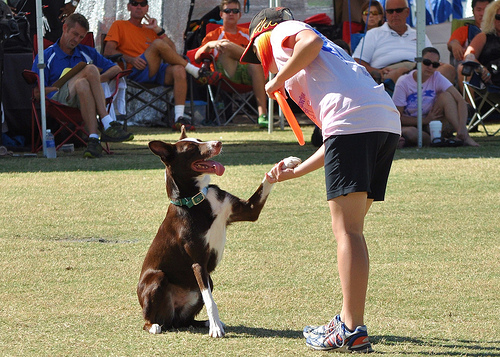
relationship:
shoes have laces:
[299, 313, 373, 353] [323, 316, 346, 346]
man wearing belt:
[352, 0, 434, 87] [385, 58, 415, 69]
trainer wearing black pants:
[239, 6, 403, 350] [323, 131, 401, 202]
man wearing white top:
[352, 0, 434, 87] [352, 25, 435, 71]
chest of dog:
[194, 205, 229, 269] [136, 125, 301, 339]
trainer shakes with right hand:
[239, 6, 403, 350] [264, 162, 297, 184]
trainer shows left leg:
[239, 6, 403, 350] [301, 137, 370, 352]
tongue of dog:
[201, 158, 226, 177] [136, 125, 301, 339]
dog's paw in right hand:
[267, 155, 303, 172] [264, 162, 297, 184]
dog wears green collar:
[136, 125, 301, 339] [166, 185, 212, 210]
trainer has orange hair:
[239, 6, 403, 350] [256, 29, 273, 76]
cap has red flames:
[238, 7, 291, 66] [247, 16, 279, 38]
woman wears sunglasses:
[392, 46, 483, 150] [422, 58, 441, 70]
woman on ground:
[392, 46, 483, 150] [1, 125, 499, 356]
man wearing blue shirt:
[32, 12, 135, 161] [26, 41, 118, 100]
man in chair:
[32, 12, 135, 161] [22, 33, 130, 155]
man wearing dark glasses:
[352, 0, 434, 87] [383, 6, 408, 17]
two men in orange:
[102, 1, 273, 129] [119, 25, 151, 48]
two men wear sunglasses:
[102, 1, 273, 129] [126, 2, 241, 18]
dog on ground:
[136, 125, 301, 339] [1, 125, 499, 356]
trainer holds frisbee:
[239, 6, 403, 350] [272, 86, 309, 149]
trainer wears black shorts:
[239, 6, 403, 350] [323, 131, 401, 202]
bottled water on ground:
[42, 127, 60, 162] [1, 125, 499, 356]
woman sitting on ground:
[392, 46, 483, 150] [1, 125, 499, 356]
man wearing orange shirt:
[102, 0, 223, 130] [107, 17, 161, 72]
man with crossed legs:
[32, 12, 135, 161] [53, 63, 136, 159]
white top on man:
[352, 25, 435, 71] [352, 0, 434, 87]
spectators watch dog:
[28, 0, 499, 156] [136, 125, 301, 339]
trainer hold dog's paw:
[239, 6, 403, 350] [267, 155, 303, 172]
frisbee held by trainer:
[272, 86, 309, 149] [239, 6, 403, 350]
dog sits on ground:
[136, 125, 301, 339] [1, 125, 499, 356]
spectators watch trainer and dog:
[28, 0, 499, 156] [137, 8, 402, 352]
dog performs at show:
[136, 125, 301, 339] [1, 0, 499, 356]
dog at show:
[136, 125, 301, 339] [1, 0, 499, 356]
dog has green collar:
[136, 125, 301, 339] [166, 185, 212, 210]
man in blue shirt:
[32, 12, 135, 161] [26, 41, 118, 100]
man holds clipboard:
[32, 12, 135, 161] [50, 61, 92, 86]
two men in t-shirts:
[102, 1, 273, 129] [103, 18, 252, 72]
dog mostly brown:
[136, 125, 301, 339] [139, 124, 207, 311]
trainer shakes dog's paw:
[239, 6, 403, 350] [270, 155, 304, 173]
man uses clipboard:
[32, 12, 135, 161] [50, 61, 92, 86]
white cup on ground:
[428, 120, 444, 146] [1, 125, 499, 356]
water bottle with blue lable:
[42, 127, 60, 162] [43, 138, 58, 148]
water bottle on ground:
[42, 127, 60, 162] [1, 125, 499, 356]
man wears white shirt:
[352, 0, 434, 87] [352, 25, 435, 71]